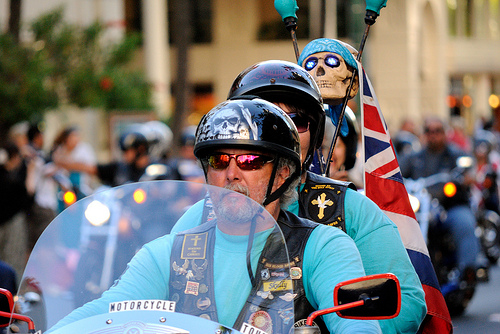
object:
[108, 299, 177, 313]
word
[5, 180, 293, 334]
windshield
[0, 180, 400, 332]
motorcycle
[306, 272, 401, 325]
left side mirror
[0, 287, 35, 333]
right side mirror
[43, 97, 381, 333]
man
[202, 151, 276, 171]
sunglasses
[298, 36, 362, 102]
skull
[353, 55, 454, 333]
flag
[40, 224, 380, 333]
shirt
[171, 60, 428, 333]
woman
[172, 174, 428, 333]
shirt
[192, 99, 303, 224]
helmet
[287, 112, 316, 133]
sunglasses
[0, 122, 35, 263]
people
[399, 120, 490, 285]
person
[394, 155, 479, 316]
motorcycle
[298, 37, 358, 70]
bandana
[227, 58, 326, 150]
helmet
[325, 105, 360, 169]
helmet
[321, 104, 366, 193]
person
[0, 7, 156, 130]
tree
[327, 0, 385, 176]
pole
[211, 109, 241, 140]
skull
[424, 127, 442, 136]
sunglasses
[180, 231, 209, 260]
patch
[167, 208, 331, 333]
vest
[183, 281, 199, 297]
patch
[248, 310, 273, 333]
patch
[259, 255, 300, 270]
patch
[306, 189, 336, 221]
patch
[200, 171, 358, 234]
vest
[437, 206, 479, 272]
pants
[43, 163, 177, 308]
motorcycle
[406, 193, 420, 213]
headlight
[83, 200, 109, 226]
headlight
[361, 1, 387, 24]
bulb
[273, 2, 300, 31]
bulb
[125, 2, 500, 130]
building